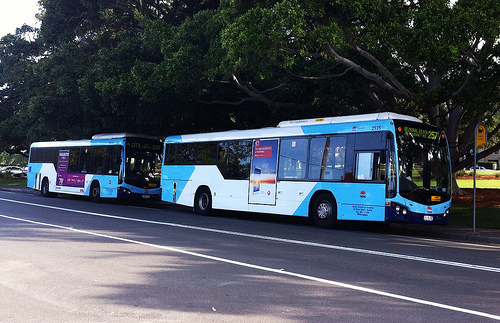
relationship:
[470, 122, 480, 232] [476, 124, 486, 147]
pole holding sign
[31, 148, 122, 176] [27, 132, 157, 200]
window on bus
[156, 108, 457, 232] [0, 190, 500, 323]
bus on pavement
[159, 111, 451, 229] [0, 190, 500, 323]
bus on pavement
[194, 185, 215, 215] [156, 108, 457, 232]
tire on side of bus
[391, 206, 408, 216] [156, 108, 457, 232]
headlight on front of bus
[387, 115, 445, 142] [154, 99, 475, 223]
sign on bus